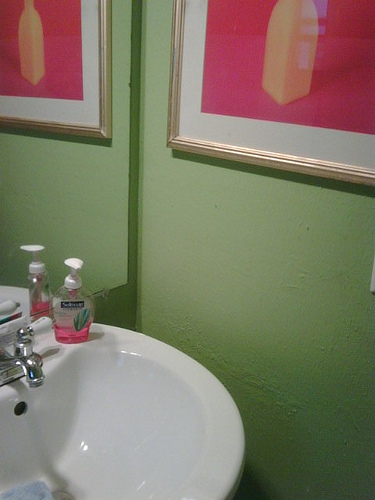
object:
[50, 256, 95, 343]
soap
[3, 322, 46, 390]
faucet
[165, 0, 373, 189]
frame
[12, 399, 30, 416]
air hole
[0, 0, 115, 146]
image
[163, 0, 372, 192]
picture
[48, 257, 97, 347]
bottle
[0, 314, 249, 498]
bathroom sink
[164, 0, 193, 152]
frame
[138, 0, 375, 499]
wall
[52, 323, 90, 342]
soap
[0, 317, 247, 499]
sink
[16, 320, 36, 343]
handle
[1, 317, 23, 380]
toothpaste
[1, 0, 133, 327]
mirror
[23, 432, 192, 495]
drain